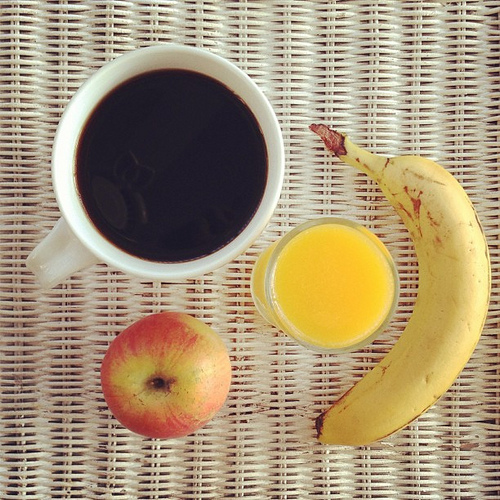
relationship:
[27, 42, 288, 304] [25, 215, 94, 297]
coffee cup has handle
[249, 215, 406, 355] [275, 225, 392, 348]
glass contains juice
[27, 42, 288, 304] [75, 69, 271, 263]
coffee cup contains coffee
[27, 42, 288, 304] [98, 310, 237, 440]
coffee cup next to apple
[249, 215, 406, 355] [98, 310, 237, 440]
glass next to apple